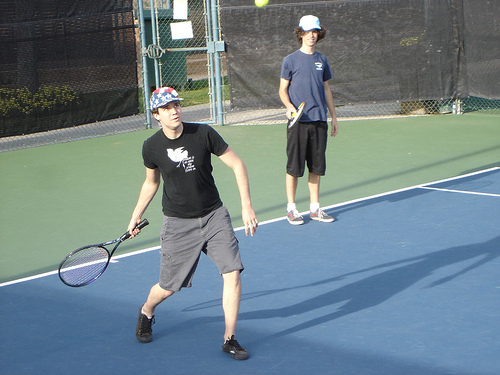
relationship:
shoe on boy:
[135, 310, 156, 344] [128, 86, 259, 361]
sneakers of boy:
[221, 334, 250, 361] [128, 86, 259, 361]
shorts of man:
[158, 205, 243, 294] [126, 84, 258, 359]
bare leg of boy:
[141, 279, 174, 318] [128, 86, 259, 361]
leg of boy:
[223, 268, 243, 340] [128, 86, 259, 361]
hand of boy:
[239, 199, 261, 241] [128, 86, 259, 361]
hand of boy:
[328, 119, 340, 138] [278, 14, 336, 227]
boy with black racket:
[128, 86, 259, 361] [57, 219, 152, 288]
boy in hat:
[124, 86, 258, 361] [151, 86, 185, 110]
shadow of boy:
[156, 236, 498, 350] [124, 86, 258, 361]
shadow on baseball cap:
[156, 236, 498, 350] [296, 15, 323, 32]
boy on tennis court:
[275, 11, 346, 231] [4, 80, 498, 372]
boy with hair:
[278, 14, 336, 227] [292, 25, 324, 40]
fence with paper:
[129, 0, 229, 141] [171, 17, 196, 47]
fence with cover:
[66, 30, 123, 95] [13, 14, 147, 159]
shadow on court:
[156, 236, 498, 350] [3, 119, 498, 374]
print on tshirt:
[161, 144, 218, 194] [143, 122, 229, 224]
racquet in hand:
[282, 102, 311, 127] [283, 106, 298, 123]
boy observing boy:
[278, 14, 336, 227] [128, 86, 259, 361]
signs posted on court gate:
[162, 0, 200, 50] [0, 2, 281, 152]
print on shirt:
[311, 57, 329, 78] [275, 46, 331, 129]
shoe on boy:
[222, 334, 249, 361] [124, 86, 258, 361]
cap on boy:
[146, 87, 183, 109] [124, 86, 258, 361]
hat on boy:
[116, 60, 193, 128] [41, 74, 311, 341]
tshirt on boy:
[138, 122, 229, 224] [124, 86, 258, 361]